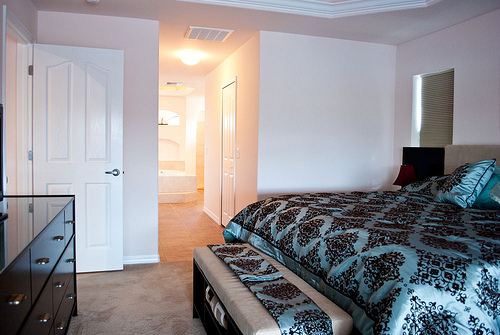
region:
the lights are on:
[163, 30, 227, 138]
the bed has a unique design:
[241, 178, 476, 333]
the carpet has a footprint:
[121, 306, 238, 333]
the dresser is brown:
[8, 174, 93, 331]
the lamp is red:
[357, 147, 465, 211]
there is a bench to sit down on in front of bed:
[170, 238, 362, 331]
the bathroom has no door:
[138, 48, 237, 243]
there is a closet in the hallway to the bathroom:
[209, 83, 250, 255]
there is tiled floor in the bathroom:
[161, 189, 228, 264]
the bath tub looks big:
[155, 157, 208, 209]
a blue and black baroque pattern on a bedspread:
[320, 200, 496, 330]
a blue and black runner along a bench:
[210, 245, 302, 333]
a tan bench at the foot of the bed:
[175, 229, 368, 330]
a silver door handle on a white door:
[83, 157, 128, 182]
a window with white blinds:
[407, 69, 460, 141]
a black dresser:
[7, 189, 98, 332]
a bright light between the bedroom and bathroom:
[157, 38, 230, 77]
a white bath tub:
[160, 147, 199, 205]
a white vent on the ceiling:
[175, 19, 244, 47]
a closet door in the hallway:
[206, 78, 241, 223]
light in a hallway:
[144, 19, 281, 236]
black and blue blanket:
[287, 150, 498, 303]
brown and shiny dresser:
[2, 174, 99, 303]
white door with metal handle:
[1, 32, 128, 292]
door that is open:
[6, 35, 146, 187]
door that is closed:
[205, 66, 274, 251]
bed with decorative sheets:
[225, 103, 491, 333]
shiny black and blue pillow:
[332, 97, 493, 247]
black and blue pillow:
[408, 131, 493, 192]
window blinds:
[400, 63, 479, 163]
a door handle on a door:
[101, 154, 124, 185]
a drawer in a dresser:
[48, 207, 79, 254]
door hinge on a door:
[25, 40, 44, 91]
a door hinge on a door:
[25, 148, 39, 168]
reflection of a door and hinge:
[23, 200, 54, 221]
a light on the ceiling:
[174, 46, 211, 76]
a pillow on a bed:
[436, 167, 483, 214]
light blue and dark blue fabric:
[320, 200, 373, 248]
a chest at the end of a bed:
[183, 236, 225, 318]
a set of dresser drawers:
[30, 202, 97, 325]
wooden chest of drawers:
[4, 189, 79, 331]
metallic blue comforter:
[210, 161, 497, 333]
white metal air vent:
[174, 15, 236, 57]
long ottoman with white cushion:
[193, 231, 343, 333]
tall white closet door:
[208, 77, 248, 234]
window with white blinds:
[403, 65, 468, 183]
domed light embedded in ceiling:
[169, 45, 214, 70]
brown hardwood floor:
[155, 195, 227, 260]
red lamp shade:
[393, 162, 418, 191]